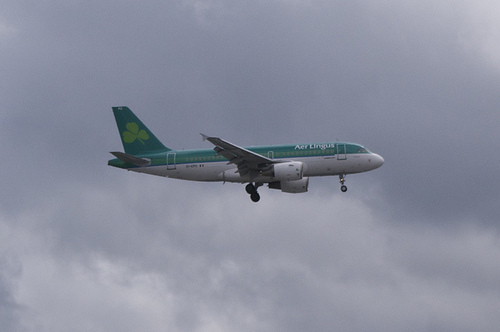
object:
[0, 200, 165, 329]
clouds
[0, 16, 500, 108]
sky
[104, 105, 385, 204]
plane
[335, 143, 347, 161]
door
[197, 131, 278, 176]
wing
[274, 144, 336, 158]
windows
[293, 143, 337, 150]
writing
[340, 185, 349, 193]
tires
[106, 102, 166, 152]
tail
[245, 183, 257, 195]
wheels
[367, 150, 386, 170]
nose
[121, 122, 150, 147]
clover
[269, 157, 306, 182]
enigine